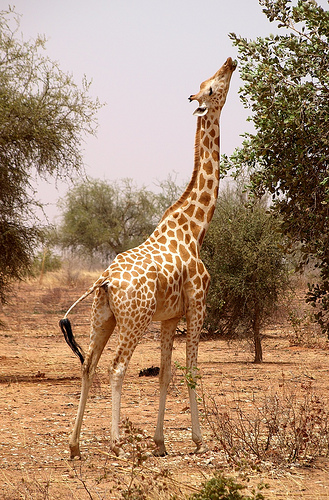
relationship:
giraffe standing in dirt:
[53, 53, 239, 458] [1, 286, 326, 498]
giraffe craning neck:
[53, 53, 239, 458] [157, 110, 222, 249]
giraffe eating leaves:
[53, 53, 239, 458] [215, 0, 328, 342]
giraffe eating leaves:
[53, 53, 239, 458] [265, 120, 310, 212]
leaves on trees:
[265, 120, 310, 212] [234, 16, 328, 327]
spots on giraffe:
[136, 242, 194, 306] [53, 53, 239, 458]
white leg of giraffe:
[187, 381, 203, 441] [53, 53, 239, 458]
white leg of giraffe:
[155, 380, 165, 441] [53, 53, 239, 458]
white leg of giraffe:
[111, 365, 121, 445] [53, 53, 239, 458]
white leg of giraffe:
[68, 375, 91, 442] [53, 53, 239, 458]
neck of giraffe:
[182, 115, 218, 211] [53, 53, 239, 458]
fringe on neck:
[170, 117, 199, 214] [182, 115, 218, 211]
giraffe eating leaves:
[53, 53, 239, 458] [232, 29, 273, 84]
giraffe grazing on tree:
[53, 53, 239, 458] [216, 0, 325, 338]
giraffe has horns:
[53, 53, 239, 458] [183, 92, 197, 104]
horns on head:
[183, 92, 197, 104] [180, 71, 219, 106]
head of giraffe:
[180, 71, 219, 106] [53, 53, 239, 458]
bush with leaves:
[209, 391, 326, 472] [264, 371, 326, 443]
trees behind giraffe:
[243, 12, 308, 282] [53, 53, 239, 458]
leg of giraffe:
[66, 301, 116, 459] [53, 53, 239, 458]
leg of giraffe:
[109, 298, 153, 460] [53, 53, 239, 458]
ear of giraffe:
[194, 103, 210, 116] [54, 51, 210, 458]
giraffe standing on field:
[53, 53, 239, 458] [37, 380, 252, 484]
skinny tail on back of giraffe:
[46, 263, 108, 370] [53, 53, 239, 458]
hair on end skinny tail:
[58, 318, 87, 364] [58, 263, 108, 368]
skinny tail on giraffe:
[58, 263, 108, 368] [53, 53, 239, 458]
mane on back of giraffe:
[180, 120, 215, 171] [53, 53, 239, 458]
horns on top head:
[188, 92, 197, 102] [183, 57, 237, 118]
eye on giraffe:
[206, 83, 213, 101] [53, 53, 239, 458]